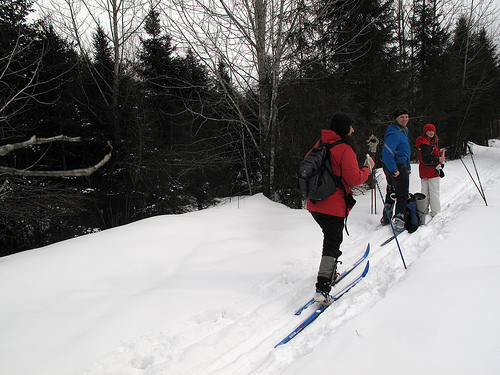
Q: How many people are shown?
A: Three.